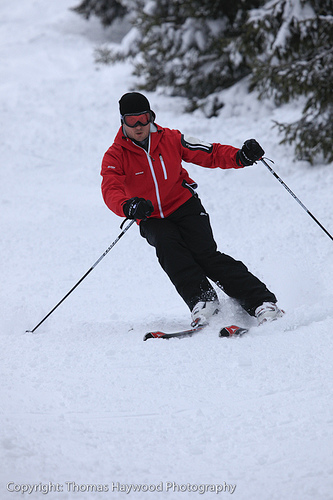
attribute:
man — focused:
[102, 92, 279, 328]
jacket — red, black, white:
[102, 129, 241, 222]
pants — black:
[138, 192, 277, 316]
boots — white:
[191, 300, 280, 327]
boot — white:
[249, 291, 279, 324]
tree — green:
[246, 0, 333, 165]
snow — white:
[242, 1, 318, 52]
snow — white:
[286, 264, 333, 456]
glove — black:
[237, 135, 265, 169]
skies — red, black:
[145, 324, 262, 341]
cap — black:
[120, 94, 152, 117]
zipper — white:
[144, 149, 163, 220]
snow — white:
[2, 4, 69, 267]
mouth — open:
[131, 129, 145, 139]